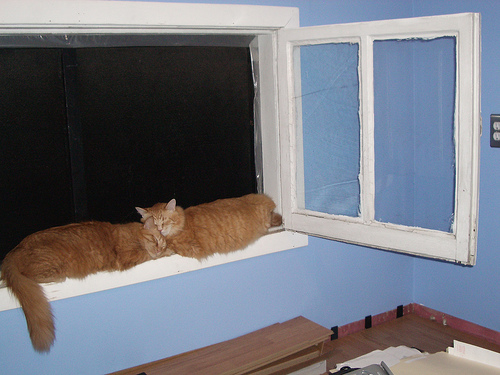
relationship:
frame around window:
[239, 16, 313, 208] [8, 8, 318, 304]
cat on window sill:
[0, 222, 169, 357] [0, 227, 290, 311]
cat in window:
[134, 192, 281, 263] [5, 37, 268, 291]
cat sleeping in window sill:
[0, 222, 169, 357] [7, 266, 181, 305]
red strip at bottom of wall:
[329, 299, 499, 341] [290, 238, 490, 310]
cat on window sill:
[47, 225, 207, 274] [0, 257, 190, 303]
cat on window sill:
[134, 192, 281, 263] [156, 241, 297, 274]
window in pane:
[299, 35, 364, 244] [297, 40, 358, 210]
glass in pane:
[370, 42, 448, 229] [365, 21, 476, 278]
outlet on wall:
[487, 112, 500, 151] [473, 17, 497, 326]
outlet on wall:
[486, 116, 497, 152] [0, 0, 498, 374]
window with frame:
[9, 16, 444, 284] [0, 0, 480, 314]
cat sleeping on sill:
[147, 200, 281, 263] [1, 226, 308, 318]